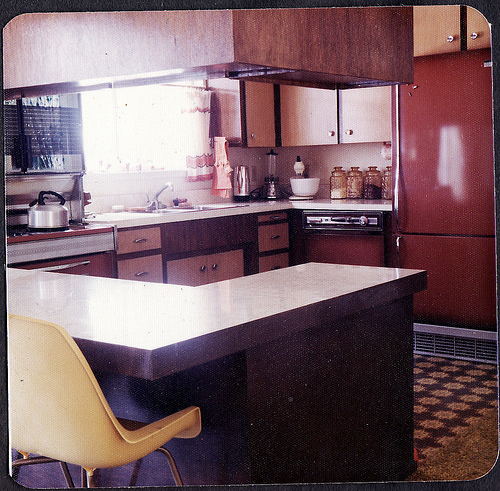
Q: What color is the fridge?
A: Red.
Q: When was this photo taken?
A: Daytime.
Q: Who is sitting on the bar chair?
A: No one.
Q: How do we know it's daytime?
A: Sun in window.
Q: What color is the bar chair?
A: Yellow.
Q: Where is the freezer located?
A: Under fridge.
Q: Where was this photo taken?
A: Kitchen.